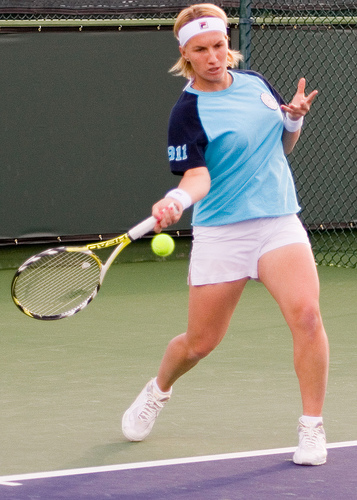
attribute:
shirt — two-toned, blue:
[169, 67, 301, 224]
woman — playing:
[13, 3, 354, 468]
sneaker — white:
[293, 419, 327, 464]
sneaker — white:
[121, 376, 171, 442]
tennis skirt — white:
[186, 211, 310, 285]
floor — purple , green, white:
[1, 236, 356, 499]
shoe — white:
[290, 411, 332, 472]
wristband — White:
[165, 187, 192, 208]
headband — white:
[176, 15, 228, 48]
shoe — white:
[116, 372, 177, 445]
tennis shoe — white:
[290, 415, 327, 466]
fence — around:
[244, 7, 350, 245]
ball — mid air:
[152, 234, 178, 259]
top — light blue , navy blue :
[163, 68, 302, 227]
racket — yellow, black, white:
[7, 205, 165, 323]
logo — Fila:
[198, 17, 208, 34]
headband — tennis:
[170, 14, 230, 46]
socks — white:
[130, 362, 331, 433]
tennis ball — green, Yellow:
[148, 233, 174, 257]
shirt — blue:
[161, 66, 310, 226]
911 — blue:
[167, 144, 188, 164]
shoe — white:
[290, 422, 327, 468]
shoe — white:
[122, 374, 175, 440]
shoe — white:
[121, 376, 172, 444]